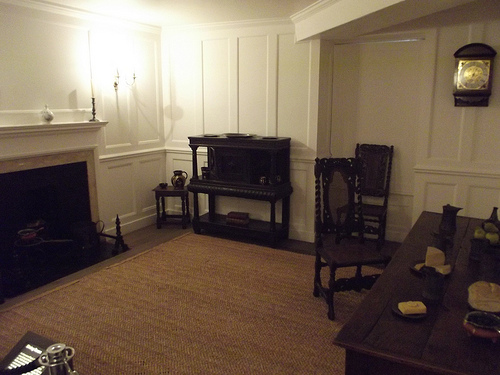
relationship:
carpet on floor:
[0, 231, 383, 375] [0, 212, 404, 372]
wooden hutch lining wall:
[185, 130, 293, 247] [164, 19, 316, 242]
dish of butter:
[389, 295, 431, 322] [399, 299, 428, 314]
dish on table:
[389, 295, 431, 322] [344, 210, 495, 369]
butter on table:
[398, 300, 428, 314] [370, 185, 497, 360]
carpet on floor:
[0, 221, 496, 370] [0, 208, 497, 373]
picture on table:
[170, 169, 192, 195] [153, 181, 195, 221]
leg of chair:
[324, 261, 334, 318] [311, 157, 392, 321]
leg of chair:
[313, 250, 323, 297] [311, 154, 392, 321]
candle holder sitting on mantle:
[88, 97, 98, 120] [0, 112, 106, 134]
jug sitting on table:
[160, 161, 198, 199] [143, 171, 210, 222]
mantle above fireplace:
[0, 117, 111, 164] [0, 117, 110, 304]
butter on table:
[398, 300, 428, 314] [344, 210, 495, 369]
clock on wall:
[445, 43, 494, 110] [434, 108, 456, 143]